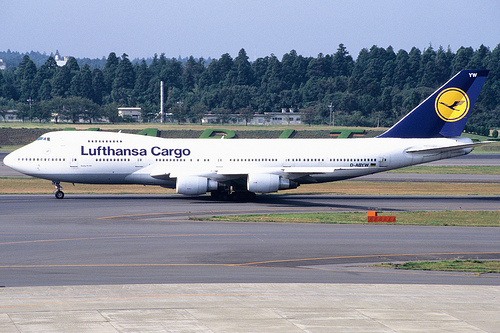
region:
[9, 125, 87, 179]
front of a plane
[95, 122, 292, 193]
body of a plane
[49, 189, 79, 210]
wheel of a plane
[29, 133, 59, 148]
window of a plane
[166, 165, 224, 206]
engine of a plane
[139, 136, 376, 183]
wing of a plane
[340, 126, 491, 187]
tail of a plane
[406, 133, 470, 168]
wing of a plane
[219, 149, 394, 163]
window of a plane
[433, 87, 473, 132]
Yellow circle symbol with bird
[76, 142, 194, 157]
Lufthansa Cargo on the side of plane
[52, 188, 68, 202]
Front wheel of plane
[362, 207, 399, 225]
Orange rectangle crate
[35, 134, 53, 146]
Front windows on the plane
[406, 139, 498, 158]
Back wing on the left side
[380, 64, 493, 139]
Blue plane tail with bird symbol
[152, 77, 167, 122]
Long metal pole in distance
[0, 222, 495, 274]
Yellow lines drawn in street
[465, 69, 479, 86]
Letter YW on the tale of the plane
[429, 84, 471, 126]
yellow logo on plane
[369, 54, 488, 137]
plane wing is blue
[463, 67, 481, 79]
white letters on wing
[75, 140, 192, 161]
blue letters on plane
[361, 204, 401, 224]
orange object in grass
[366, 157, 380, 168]
small flag on plane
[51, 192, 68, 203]
plane wheel is out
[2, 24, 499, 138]
trees in the distance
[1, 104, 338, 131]
buildings in the distance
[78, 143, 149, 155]
bold blue text reading Lufthansa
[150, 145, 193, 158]
bold blue text reading Cargo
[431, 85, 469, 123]
yellow and blue logo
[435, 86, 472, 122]
blue bird graphic on a yellow circle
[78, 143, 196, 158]
print reading Lufthansa Cargo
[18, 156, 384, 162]
long row of plane windows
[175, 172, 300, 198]
two white plane engines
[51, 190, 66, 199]
small front plane wheel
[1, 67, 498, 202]
Lufthansa Cargo plane on a runway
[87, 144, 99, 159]
The letter is blue.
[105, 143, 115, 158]
The letter is blue.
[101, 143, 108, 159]
The letter is blue.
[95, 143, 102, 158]
The letter is blue.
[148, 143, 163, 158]
The letter is blue.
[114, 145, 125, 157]
The letter is blue.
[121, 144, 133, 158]
The letter is blue.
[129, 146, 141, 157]
The letter is blue.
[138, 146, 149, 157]
The letter is blue.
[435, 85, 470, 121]
yellow and black logo on the stabilizer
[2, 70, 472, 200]
white jet sitting on the landing strip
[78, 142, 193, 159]
airline name on the side of the plane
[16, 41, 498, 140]
trees in the distance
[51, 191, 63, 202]
front wheel of the airplane